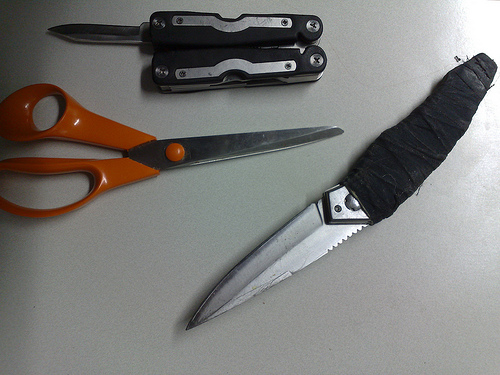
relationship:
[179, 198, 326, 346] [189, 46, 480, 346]
blade of knife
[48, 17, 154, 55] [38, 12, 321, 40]
blade of knife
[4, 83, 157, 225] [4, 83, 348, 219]
handle of scissors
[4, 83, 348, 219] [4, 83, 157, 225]
scissors has handle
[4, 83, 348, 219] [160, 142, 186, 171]
scissors has swivel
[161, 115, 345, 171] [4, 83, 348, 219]
blade on scissors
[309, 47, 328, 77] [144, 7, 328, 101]
screw on multitool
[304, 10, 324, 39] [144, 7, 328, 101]
screw on multitool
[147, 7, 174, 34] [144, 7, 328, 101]
screw on multitool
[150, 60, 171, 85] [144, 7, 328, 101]
screw on multitool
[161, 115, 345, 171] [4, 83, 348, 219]
blade of scissors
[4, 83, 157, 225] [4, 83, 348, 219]
handle on scissors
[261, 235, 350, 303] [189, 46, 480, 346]
edge of knife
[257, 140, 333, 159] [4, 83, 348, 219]
edge of scissors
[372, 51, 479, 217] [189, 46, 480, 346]
handle of knife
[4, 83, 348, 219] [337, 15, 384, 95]
scissors on table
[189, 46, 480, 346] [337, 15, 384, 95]
knife on table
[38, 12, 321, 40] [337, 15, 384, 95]
knife on table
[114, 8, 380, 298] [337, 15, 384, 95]
tools on table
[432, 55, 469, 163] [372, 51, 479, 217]
tape on handle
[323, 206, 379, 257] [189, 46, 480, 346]
serrated on knife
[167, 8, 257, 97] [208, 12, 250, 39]
handle has silver